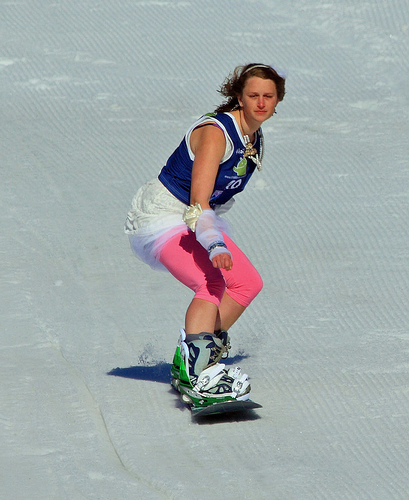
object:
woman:
[125, 62, 283, 400]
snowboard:
[165, 361, 263, 416]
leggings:
[143, 213, 264, 307]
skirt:
[123, 177, 238, 272]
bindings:
[176, 349, 250, 407]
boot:
[179, 327, 251, 404]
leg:
[154, 229, 225, 337]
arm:
[188, 126, 233, 271]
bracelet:
[203, 240, 229, 252]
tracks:
[34, 117, 135, 285]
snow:
[6, 5, 405, 496]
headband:
[240, 64, 276, 73]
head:
[237, 62, 287, 121]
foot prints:
[32, 67, 142, 116]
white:
[188, 207, 226, 256]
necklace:
[238, 108, 264, 171]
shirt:
[157, 108, 265, 208]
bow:
[182, 203, 200, 232]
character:
[232, 156, 248, 176]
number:
[224, 179, 243, 191]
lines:
[101, 19, 382, 116]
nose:
[256, 97, 266, 109]